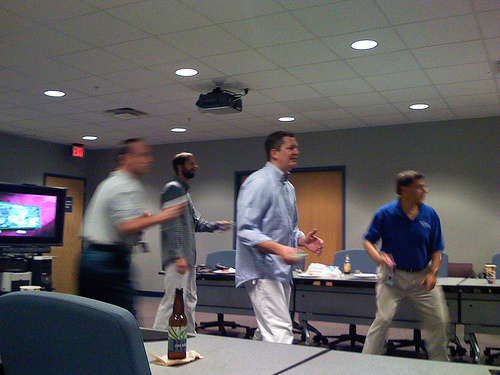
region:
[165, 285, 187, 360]
brown glass bottle on table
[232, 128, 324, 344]
man in button down blue shirt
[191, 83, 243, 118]
projector fastened to ceiling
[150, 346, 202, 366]
beige paper crumpled napkin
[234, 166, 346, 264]
wooden door against wall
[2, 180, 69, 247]
black television screen turned on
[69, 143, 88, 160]
red exit sign above door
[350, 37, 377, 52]
recessed lighting in ceiling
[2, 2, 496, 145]
drop ceiling tiles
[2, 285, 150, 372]
blue fabric chair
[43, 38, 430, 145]
seven circular ceiling lights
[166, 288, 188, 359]
brown bottle on the table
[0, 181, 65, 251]
tv monitor in the back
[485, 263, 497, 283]
plastic drink cup on the table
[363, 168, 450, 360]
man in bright blue shirt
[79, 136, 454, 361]
four men in a room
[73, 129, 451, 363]
four men playing a game together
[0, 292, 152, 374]
top part of chair in the lower left corner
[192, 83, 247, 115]
projector hanging from the ceiling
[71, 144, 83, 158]
red exit sign above the door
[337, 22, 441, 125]
round ceiling lights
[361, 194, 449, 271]
blue short sleeve shirt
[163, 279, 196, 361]
brown beet bottle on table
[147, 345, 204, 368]
brown napking under neath brown bottle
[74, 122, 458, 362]
group of men standing in room holding rempote controls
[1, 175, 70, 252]
black television with purple screen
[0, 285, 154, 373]
top of brown chair in conference room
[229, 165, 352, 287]
tan wood door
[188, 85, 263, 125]
projector mounted on ceiling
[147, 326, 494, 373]
grey hard surfaced table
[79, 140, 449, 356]
four men in a conference room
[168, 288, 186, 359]
beer bottle on the near table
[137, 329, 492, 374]
near gray table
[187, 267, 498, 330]
gray table across the room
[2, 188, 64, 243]
television set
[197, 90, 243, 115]
projector hanging from ceiling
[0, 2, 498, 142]
white tiled ceiling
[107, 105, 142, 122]
air conditioning vent in the ceiling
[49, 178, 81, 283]
door behind the television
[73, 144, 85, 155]
red exit sign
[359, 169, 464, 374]
man wearing a blue polo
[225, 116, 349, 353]
man wearing a light blue shirt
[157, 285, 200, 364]
a bottle of bear on the table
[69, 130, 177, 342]
guy wearing a shirt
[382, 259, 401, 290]
a badge on the belt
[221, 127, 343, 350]
guy wearing a white pant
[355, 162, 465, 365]
guy wearing a white pants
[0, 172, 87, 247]
a television set is on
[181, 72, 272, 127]
a projection display system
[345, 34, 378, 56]
light bulb on the ceiling